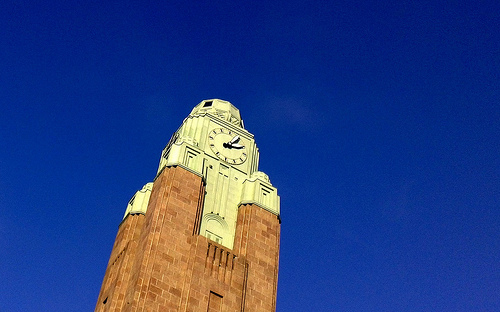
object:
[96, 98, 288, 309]
tower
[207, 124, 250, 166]
clock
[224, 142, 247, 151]
hands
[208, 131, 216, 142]
numbers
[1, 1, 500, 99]
sky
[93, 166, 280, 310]
columns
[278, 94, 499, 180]
clouds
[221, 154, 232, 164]
numerals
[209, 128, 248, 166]
time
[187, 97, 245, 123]
cap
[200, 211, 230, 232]
arch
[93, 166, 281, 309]
bricks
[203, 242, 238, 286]
ridges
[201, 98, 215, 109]
square